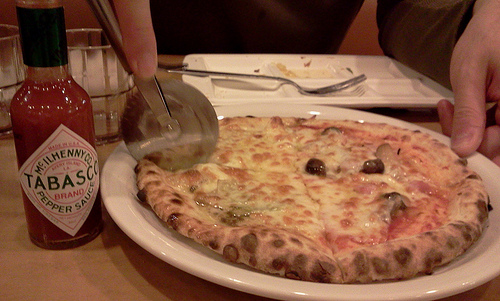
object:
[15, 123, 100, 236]
label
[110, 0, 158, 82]
finger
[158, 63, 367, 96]
fork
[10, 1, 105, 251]
sauce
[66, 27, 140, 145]
glass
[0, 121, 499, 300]
table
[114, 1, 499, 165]
person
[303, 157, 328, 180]
sausage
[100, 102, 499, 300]
plate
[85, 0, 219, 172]
cutter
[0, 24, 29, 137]
glasses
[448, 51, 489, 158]
thumb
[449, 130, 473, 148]
nail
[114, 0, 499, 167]
man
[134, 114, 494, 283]
food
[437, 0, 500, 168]
hand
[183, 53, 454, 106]
plate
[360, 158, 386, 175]
sausage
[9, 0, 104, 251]
bottle